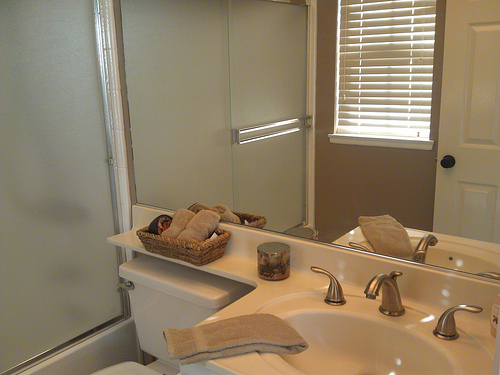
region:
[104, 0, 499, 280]
large mirror in bathroom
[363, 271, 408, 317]
a brushed steel faucet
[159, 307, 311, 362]
a grey hand towel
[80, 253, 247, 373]
a white toilet in bathroom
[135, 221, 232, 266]
a woven, rectangular basket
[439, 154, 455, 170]
a black door knob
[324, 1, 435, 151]
a narrow window with shutters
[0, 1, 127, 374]
a shower with frosted glass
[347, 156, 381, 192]
a dark grey wall reflected in mirror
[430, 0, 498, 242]
a white bathroom door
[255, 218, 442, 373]
The sink is visible.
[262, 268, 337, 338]
The sink is visible.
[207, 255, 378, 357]
The sink is visible.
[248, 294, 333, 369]
The sink is visible.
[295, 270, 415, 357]
The sink is visible.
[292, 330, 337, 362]
The sink is visible.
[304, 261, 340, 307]
silver handle on sink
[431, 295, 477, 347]
silver handle on sink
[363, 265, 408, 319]
silver faucet of sink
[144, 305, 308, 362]
taupe hand towel on sink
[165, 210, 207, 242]
taupe towels in basket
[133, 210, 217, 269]
brown basket on side of sink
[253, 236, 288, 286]
candle with metal top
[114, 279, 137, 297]
silver lever on toilet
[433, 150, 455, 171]
brown door handle on door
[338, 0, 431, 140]
white blind on window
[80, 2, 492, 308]
Mirror reflecting bathroom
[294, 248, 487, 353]
Steel fixtures in sink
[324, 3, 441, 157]
Blinds pulled down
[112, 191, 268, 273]
Towels in a basket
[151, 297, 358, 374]
Towel on the edge of sink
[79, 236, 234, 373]
Toilet bowl along side of sink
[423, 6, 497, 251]
Door in reflection is open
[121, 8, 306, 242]
Smoked glass shower door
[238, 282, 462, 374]
Oval shaped sink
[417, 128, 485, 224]
Black door knob white door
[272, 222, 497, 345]
a silver bathroom faucet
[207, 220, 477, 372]
a white bathroom sink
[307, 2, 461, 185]
a small bathroom window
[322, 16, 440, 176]
a small window with light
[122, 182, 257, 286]
wicker basket on shelf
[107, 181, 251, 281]
wicker basket above toilet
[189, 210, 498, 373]
a sink in the bathroom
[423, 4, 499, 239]
an open white door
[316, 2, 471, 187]
a window in the bathroom